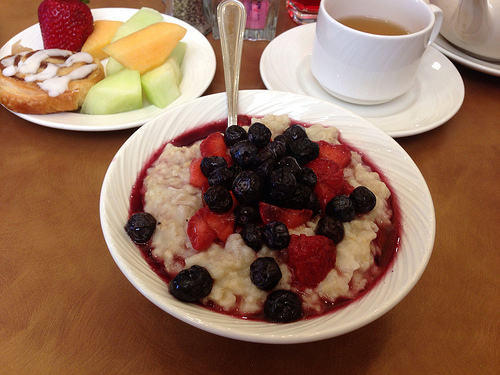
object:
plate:
[259, 22, 465, 138]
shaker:
[164, 0, 211, 35]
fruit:
[123, 121, 376, 325]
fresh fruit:
[0, 0, 187, 115]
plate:
[0, 8, 216, 131]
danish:
[0, 49, 105, 115]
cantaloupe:
[140, 63, 180, 109]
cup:
[311, 0, 443, 106]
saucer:
[258, 22, 463, 139]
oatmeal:
[123, 113, 404, 325]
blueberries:
[167, 263, 213, 303]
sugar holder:
[236, 0, 283, 42]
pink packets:
[239, 0, 272, 30]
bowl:
[99, 88, 436, 344]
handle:
[215, 0, 246, 129]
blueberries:
[122, 211, 157, 244]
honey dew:
[80, 70, 144, 116]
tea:
[331, 16, 414, 37]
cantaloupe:
[102, 21, 187, 75]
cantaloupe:
[108, 6, 163, 44]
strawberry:
[36, 0, 95, 54]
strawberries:
[186, 131, 357, 287]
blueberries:
[263, 290, 304, 325]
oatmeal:
[147, 168, 183, 203]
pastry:
[0, 43, 104, 116]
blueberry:
[250, 256, 283, 291]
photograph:
[0, 0, 500, 375]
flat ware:
[214, 0, 247, 129]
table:
[0, 0, 500, 375]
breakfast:
[0, 0, 466, 346]